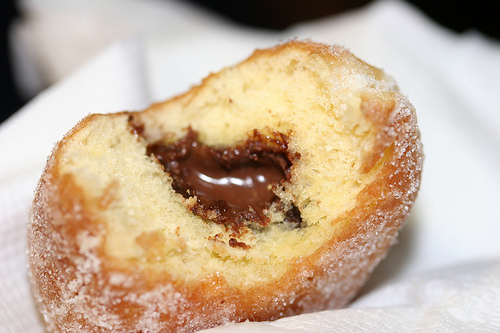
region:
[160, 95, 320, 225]
chocolate in the bread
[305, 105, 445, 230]
dark and light bread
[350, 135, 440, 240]
white sugar on the bread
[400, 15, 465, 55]
blurry background of photo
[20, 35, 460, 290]
food with bite taken out of it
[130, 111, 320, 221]
inner part of the bread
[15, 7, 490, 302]
photo with no people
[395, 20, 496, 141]
white napkin under bread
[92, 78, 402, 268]
bread with chocolate in the middle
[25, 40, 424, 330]
a chocolate filled donut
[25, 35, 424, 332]
a sugar chocolate filled donut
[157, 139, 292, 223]
chocolate inside a donut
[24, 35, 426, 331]
a bitten chocolate filled donut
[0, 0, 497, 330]
a chocolate filled donut on a white napkin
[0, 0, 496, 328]
a donut on top of a napkin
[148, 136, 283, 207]
chocolate in a donut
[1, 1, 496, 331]
a donut on a napkin in a person's hand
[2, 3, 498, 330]
a person holding a chocolate filled donut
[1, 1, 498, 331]
a white napkin under a chocolate filled donut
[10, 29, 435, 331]
this is a donut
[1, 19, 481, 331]
the donut is wrapped in a napkin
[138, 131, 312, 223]
the chocolate center of a donut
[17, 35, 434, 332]
the donut has been bitten into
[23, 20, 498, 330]
the donut has a filling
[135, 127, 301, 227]
this is a chocolate filling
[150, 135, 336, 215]
a chocolate cream filling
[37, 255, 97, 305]
this is sugar on the donut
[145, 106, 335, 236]
chocolate in the donut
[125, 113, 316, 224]
this is the filling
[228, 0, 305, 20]
black background of photo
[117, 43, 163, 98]
crease in white material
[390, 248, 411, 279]
shadow of the dessert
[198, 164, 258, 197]
chocolate in the center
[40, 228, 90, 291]
white crystals of probably sugar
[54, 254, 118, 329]
white flakes stuck on outside of dessert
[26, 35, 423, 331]
sweet food for dessert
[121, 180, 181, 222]
inner bread of pastry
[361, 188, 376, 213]
golden outside layer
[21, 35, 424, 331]
the item was maybe fried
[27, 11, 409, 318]
chocolate filling in sugary pastry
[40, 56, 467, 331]
chocolate filling in sugary pastry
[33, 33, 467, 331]
chocolate filling in sugary pastry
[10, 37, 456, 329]
chocolate filling in sugary pastry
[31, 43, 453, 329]
chocolate filling in sugary pastry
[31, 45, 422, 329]
chocolate filling in sugary pastry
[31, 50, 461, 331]
chocolate filling in sugary pastry